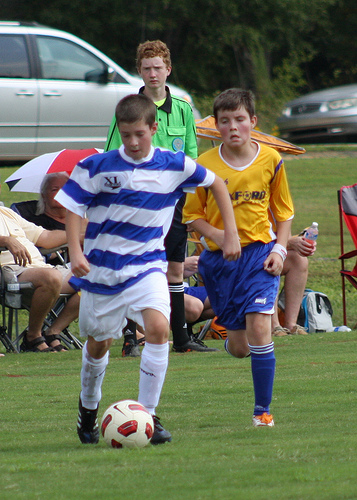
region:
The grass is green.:
[193, 443, 347, 492]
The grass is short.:
[217, 442, 329, 490]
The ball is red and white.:
[90, 387, 163, 452]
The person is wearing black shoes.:
[51, 388, 183, 463]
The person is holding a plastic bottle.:
[298, 219, 322, 260]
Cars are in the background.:
[258, 57, 356, 148]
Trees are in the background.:
[206, 3, 337, 73]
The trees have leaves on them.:
[213, 3, 323, 66]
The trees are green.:
[216, 6, 324, 61]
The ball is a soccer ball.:
[93, 395, 164, 459]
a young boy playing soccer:
[61, 98, 240, 446]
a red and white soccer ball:
[95, 398, 153, 449]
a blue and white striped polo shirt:
[63, 156, 213, 288]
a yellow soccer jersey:
[178, 141, 296, 251]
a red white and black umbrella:
[7, 149, 101, 195]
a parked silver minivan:
[0, 19, 199, 160]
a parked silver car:
[276, 80, 355, 143]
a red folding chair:
[334, 181, 356, 328]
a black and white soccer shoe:
[73, 394, 97, 446]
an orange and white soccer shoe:
[250, 414, 274, 430]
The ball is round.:
[90, 390, 163, 456]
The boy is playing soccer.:
[54, 90, 244, 457]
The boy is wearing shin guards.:
[51, 90, 242, 445]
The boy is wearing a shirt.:
[46, 88, 245, 452]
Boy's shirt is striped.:
[38, 91, 252, 456]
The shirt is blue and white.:
[45, 92, 246, 305]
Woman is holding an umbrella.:
[2, 137, 123, 266]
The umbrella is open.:
[5, 139, 114, 258]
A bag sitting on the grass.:
[278, 272, 355, 348]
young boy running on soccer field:
[178, 78, 304, 454]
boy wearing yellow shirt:
[184, 80, 310, 439]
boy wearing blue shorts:
[180, 77, 307, 445]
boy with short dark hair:
[182, 75, 310, 454]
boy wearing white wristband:
[189, 77, 306, 436]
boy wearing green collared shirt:
[106, 28, 201, 365]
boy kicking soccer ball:
[49, 81, 240, 448]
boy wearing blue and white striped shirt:
[58, 81, 241, 464]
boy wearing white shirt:
[54, 80, 245, 457]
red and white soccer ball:
[93, 392, 166, 464]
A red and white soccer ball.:
[97, 384, 167, 457]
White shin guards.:
[57, 341, 174, 426]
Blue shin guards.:
[227, 330, 284, 421]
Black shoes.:
[75, 389, 179, 458]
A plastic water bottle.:
[293, 218, 330, 271]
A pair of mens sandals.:
[13, 328, 80, 359]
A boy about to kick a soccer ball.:
[39, 97, 230, 479]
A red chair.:
[332, 178, 355, 324]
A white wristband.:
[264, 244, 290, 259]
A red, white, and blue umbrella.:
[2, 138, 149, 223]